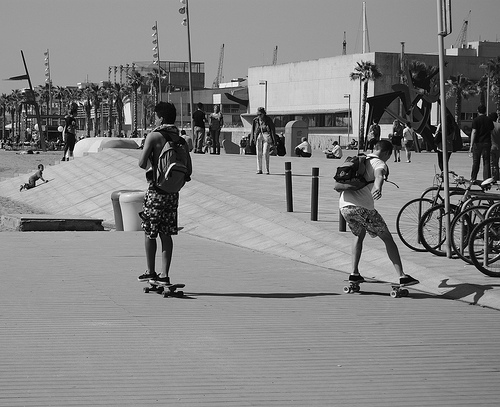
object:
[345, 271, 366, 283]
sneakers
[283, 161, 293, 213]
poles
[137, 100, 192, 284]
man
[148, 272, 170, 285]
shoes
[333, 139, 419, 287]
boy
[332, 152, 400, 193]
backpack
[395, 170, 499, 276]
bicycles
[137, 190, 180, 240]
shorts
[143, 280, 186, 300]
skateboard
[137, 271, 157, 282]
shoes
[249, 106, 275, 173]
woman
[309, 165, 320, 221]
black poles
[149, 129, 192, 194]
backpack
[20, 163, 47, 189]
child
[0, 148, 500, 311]
slope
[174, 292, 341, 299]
shadow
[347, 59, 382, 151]
palm tree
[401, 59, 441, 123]
palm tree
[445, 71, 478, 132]
palm tree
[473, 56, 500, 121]
palm tree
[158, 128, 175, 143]
black strap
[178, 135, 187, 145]
black strap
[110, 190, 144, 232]
cans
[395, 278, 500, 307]
shadow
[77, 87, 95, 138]
palm tree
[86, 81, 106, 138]
palm tree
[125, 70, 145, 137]
palm tree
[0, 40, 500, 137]
building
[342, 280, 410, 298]
skateboard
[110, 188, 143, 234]
trashcan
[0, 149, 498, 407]
sidewalk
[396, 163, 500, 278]
rack